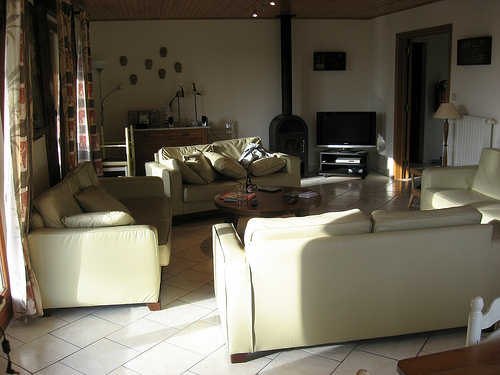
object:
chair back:
[467, 296, 499, 344]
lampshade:
[432, 103, 463, 120]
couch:
[420, 147, 499, 230]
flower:
[19, 151, 29, 168]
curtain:
[54, 5, 101, 182]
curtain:
[3, 1, 42, 321]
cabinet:
[132, 128, 209, 176]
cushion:
[177, 157, 207, 185]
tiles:
[6, 313, 68, 344]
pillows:
[203, 150, 247, 180]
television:
[316, 111, 377, 148]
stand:
[319, 148, 369, 177]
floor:
[0, 187, 491, 375]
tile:
[103, 318, 180, 353]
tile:
[61, 337, 141, 374]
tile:
[256, 349, 342, 373]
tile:
[328, 348, 400, 373]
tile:
[164, 319, 226, 356]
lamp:
[94, 60, 127, 127]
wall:
[87, 21, 378, 171]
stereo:
[128, 111, 160, 128]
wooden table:
[214, 185, 323, 241]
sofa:
[143, 136, 301, 217]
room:
[0, 0, 498, 374]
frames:
[313, 50, 347, 71]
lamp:
[432, 103, 460, 167]